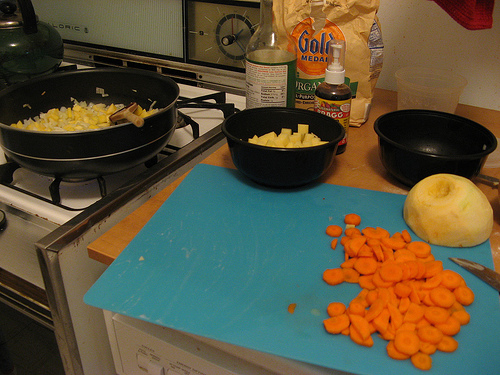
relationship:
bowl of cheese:
[371, 108, 498, 191] [253, 127, 296, 149]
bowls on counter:
[238, 107, 458, 188] [342, 140, 373, 186]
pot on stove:
[63, 76, 195, 156] [23, 171, 129, 224]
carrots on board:
[353, 235, 459, 367] [284, 200, 316, 244]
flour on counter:
[273, 6, 373, 72] [342, 140, 373, 186]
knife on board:
[452, 254, 498, 289] [284, 200, 316, 244]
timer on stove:
[215, 13, 251, 54] [23, 171, 129, 224]